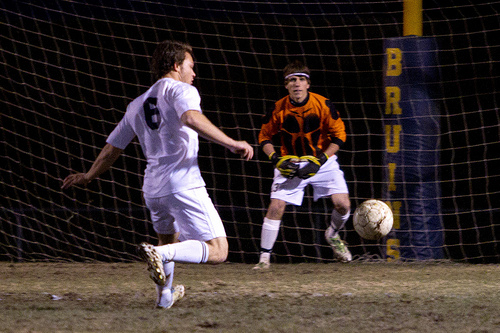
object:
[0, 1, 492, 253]
net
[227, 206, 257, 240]
hole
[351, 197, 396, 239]
ball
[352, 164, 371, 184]
hole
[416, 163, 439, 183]
hole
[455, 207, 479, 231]
hole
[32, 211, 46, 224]
hole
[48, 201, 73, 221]
hole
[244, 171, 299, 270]
leg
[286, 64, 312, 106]
head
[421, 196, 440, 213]
hole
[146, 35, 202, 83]
head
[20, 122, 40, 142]
square hole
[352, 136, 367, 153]
hole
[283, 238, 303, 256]
hole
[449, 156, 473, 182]
square hole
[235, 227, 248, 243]
hole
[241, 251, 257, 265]
hole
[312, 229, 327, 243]
hole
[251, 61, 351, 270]
man